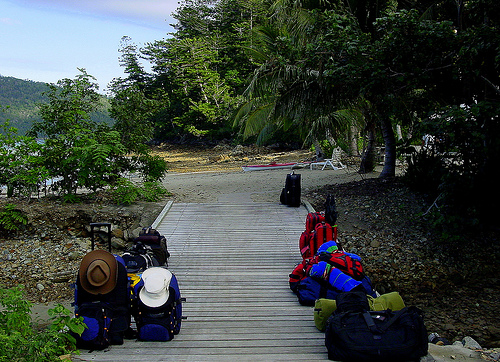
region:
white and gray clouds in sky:
[11, 6, 115, 68]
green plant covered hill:
[3, 84, 33, 122]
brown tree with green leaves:
[42, 75, 103, 187]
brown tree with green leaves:
[123, 72, 243, 141]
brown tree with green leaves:
[191, 6, 307, 133]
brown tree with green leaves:
[276, 10, 477, 100]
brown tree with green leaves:
[400, 82, 490, 248]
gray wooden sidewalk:
[188, 195, 278, 354]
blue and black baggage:
[86, 230, 178, 348]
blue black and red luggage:
[296, 203, 416, 359]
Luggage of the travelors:
[76, 168, 368, 360]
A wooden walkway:
[130, 184, 317, 360]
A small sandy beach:
[123, 133, 365, 210]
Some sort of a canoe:
[218, 153, 312, 178]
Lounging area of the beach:
[302, 141, 433, 171]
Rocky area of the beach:
[6, 197, 108, 281]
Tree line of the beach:
[115, 73, 420, 136]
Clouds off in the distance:
[90, 5, 164, 40]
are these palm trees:
[265, 50, 440, 167]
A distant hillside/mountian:
[3, 59, 83, 138]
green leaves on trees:
[184, 32, 286, 82]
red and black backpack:
[306, 218, 342, 262]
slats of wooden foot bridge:
[177, 196, 282, 358]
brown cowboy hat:
[77, 245, 119, 297]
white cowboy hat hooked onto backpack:
[134, 259, 174, 307]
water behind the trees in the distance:
[12, 137, 127, 178]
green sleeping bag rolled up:
[312, 287, 405, 334]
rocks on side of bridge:
[12, 237, 80, 281]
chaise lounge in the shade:
[309, 143, 351, 172]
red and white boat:
[239, 158, 303, 170]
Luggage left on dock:
[71, 212, 196, 334]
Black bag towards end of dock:
[283, 167, 308, 209]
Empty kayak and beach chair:
[248, 144, 360, 174]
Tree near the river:
[39, 78, 164, 197]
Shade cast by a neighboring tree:
[361, 128, 499, 263]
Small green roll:
[303, 286, 403, 310]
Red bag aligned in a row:
[291, 202, 363, 272]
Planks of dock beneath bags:
[190, 203, 295, 351]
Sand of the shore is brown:
[191, 168, 281, 195]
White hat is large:
[134, 260, 179, 301]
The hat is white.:
[138, 259, 177, 310]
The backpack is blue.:
[130, 264, 187, 343]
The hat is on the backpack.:
[131, 260, 188, 344]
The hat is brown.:
[75, 244, 121, 297]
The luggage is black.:
[284, 168, 304, 208]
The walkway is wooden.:
[81, 170, 342, 360]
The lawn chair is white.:
[306, 143, 349, 175]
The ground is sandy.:
[136, 164, 386, 201]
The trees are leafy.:
[5, 71, 165, 214]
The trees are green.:
[2, 66, 168, 211]